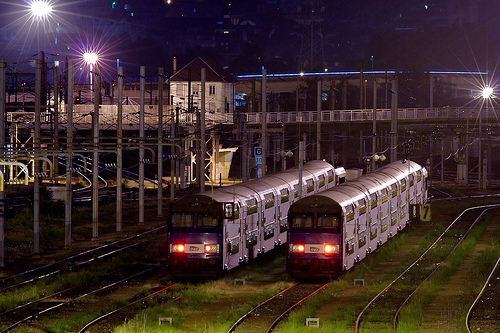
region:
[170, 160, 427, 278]
two train cars are parked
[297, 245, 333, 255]
the lights are on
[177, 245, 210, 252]
the lights are orange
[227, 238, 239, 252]
window on the train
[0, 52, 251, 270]
the fence is tall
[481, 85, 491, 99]
the light is bright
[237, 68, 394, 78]
a line of blue lights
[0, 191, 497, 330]
train tracks on ground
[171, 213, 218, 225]
front windows of train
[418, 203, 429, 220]
number 7 on a sign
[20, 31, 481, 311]
The trains are traveling to the city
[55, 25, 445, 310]
The trains both have their lights on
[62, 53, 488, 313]
The trains are parked at the station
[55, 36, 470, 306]
Some trains are parked next to each other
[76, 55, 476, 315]
The trains carry many people each day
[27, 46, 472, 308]
The trains are both on the railroad tracks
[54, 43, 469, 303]
The trains are both parked for repairs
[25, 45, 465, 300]
The train cars are designed for passengers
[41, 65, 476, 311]
The train cars have many windows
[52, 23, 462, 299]
The train cars are guarded at nighttime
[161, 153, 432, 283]
Two trains on the tracks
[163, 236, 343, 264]
Bright lights on the fronts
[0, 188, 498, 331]
Many rail tracks side by side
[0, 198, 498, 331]
Short green grass growing between the rails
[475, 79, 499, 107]
Very bright white light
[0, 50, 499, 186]
Long white colored building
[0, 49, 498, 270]
Lines of tall poles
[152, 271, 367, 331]
Metal marks stuck on the gound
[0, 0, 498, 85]
Blue colored background with spots of lighting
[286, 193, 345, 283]
Front section of a train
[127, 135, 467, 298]
there are two trains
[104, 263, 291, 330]
patches of grass are growing in between the tracks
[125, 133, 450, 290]
the trains are on different rails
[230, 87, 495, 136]
this is a raised walkway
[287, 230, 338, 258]
two bright red tail lights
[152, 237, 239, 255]
the train's tail lights are on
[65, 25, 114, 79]
bright lights on a lamppost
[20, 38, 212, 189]
this is electrical wire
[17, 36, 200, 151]
these are powerlines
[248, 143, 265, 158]
the letter "G" on a sign